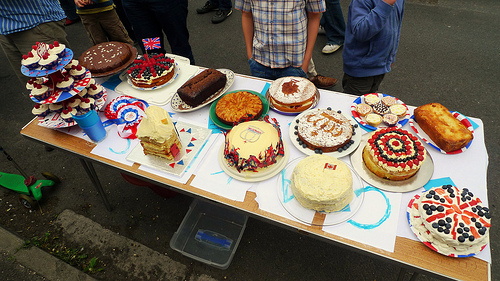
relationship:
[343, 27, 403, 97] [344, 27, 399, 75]
person wearing blue shirt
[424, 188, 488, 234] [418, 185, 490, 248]
strawberries on cake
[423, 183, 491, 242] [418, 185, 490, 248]
blueberries on cake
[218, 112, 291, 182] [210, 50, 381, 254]
cake on table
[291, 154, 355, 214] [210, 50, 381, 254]
cake on table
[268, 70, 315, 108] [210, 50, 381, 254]
cake on table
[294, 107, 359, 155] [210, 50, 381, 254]
cake on table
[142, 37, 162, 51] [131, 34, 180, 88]
flag in cake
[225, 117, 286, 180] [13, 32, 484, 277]
cake on table top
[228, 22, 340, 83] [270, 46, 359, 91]
hands in pockets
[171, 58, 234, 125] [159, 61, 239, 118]
dessert on plate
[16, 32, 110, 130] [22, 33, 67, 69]
cupcakes tower with icing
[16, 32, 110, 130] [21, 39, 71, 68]
cupcakes tower with berries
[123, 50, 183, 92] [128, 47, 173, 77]
cake with berries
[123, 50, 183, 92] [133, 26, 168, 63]
cake with flag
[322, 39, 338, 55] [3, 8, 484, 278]
shoe on ground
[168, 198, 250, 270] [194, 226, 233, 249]
box with label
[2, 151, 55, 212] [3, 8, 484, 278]
scooter on ground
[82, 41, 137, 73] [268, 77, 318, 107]
cake with sprinkles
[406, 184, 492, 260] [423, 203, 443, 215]
cake with blueberries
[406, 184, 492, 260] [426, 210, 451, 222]
cake with red stripes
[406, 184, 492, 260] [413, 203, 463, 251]
cake with white icing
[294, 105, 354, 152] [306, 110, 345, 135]
cake has crown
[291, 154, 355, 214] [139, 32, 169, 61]
cake has flag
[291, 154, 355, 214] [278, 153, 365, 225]
cake on plate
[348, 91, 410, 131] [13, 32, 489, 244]
plates with cakes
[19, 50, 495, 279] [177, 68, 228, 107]
table full of dessert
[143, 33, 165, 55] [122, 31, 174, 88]
flag on cake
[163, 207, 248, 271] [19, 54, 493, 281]
box under table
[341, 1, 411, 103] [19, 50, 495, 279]
person standing in front of table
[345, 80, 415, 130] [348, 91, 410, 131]
plate of cupcakes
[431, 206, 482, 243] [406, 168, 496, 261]
balls on cake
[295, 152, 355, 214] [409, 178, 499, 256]
cake with cake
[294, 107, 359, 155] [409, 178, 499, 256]
cake with cake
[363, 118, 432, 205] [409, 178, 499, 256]
cake with cake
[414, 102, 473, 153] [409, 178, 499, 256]
bread with cake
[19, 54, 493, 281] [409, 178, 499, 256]
table with cake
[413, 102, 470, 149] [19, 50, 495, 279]
bread on table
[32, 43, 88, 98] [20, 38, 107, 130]
muffins stacked on platter